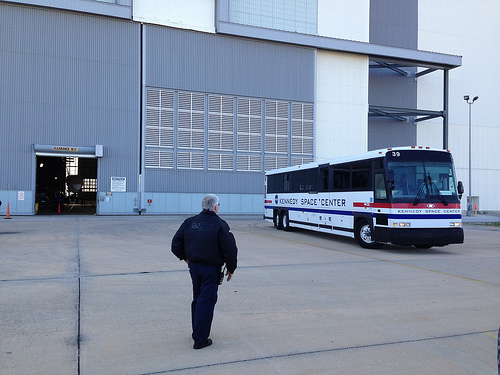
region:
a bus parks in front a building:
[232, 50, 482, 257]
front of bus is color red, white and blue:
[380, 140, 466, 250]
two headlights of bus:
[386, 216, 467, 231]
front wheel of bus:
[346, 215, 379, 246]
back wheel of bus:
[268, 202, 295, 235]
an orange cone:
[3, 197, 14, 224]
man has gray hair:
[175, 182, 235, 253]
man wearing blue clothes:
[168, 185, 246, 355]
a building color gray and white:
[1, 33, 478, 258]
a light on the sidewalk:
[463, 82, 492, 229]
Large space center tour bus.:
[251, 135, 462, 253]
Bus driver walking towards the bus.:
[164, 193, 246, 354]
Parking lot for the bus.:
[274, 255, 462, 353]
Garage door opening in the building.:
[26, 137, 109, 213]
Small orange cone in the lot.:
[2, 199, 19, 223]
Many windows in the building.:
[133, 90, 320, 182]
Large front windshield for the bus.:
[368, 144, 456, 206]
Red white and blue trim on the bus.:
[352, 197, 475, 234]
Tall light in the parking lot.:
[459, 83, 487, 215]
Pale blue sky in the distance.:
[455, 8, 494, 60]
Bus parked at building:
[245, 118, 478, 262]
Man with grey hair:
[149, 171, 255, 360]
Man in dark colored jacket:
[156, 184, 252, 353]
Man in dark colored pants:
[149, 182, 253, 356]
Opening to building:
[15, 130, 122, 233]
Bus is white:
[249, 134, 488, 275]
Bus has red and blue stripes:
[251, 142, 476, 269]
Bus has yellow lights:
[251, 128, 476, 258]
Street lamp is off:
[448, 70, 489, 237]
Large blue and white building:
[70, 7, 443, 224]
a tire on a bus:
[359, 217, 382, 261]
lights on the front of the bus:
[381, 206, 423, 235]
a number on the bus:
[383, 139, 404, 166]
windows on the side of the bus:
[270, 170, 322, 197]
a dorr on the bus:
[372, 162, 397, 247]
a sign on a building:
[104, 161, 135, 206]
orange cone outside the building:
[2, 191, 21, 233]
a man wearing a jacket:
[160, 193, 270, 282]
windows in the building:
[151, 101, 230, 178]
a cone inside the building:
[51, 189, 78, 228]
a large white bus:
[262, 143, 462, 248]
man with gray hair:
[170, 191, 237, 346]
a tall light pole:
[460, 90, 476, 215]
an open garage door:
[32, 155, 97, 211]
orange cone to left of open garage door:
[5, 200, 11, 217]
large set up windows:
[145, 85, 310, 165]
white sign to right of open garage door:
[110, 172, 125, 192]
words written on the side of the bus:
[275, 195, 345, 205]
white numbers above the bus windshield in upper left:
[387, 147, 397, 157]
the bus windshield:
[392, 162, 452, 193]